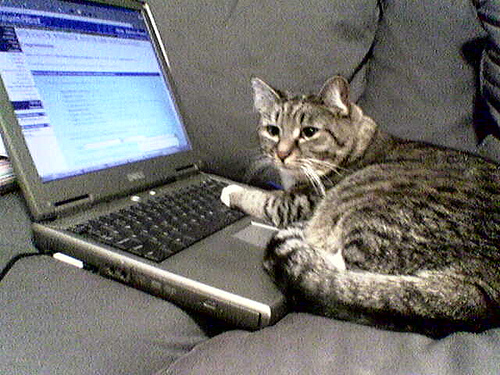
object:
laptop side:
[26, 221, 277, 329]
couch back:
[148, 1, 500, 189]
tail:
[262, 220, 500, 337]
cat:
[219, 76, 500, 330]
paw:
[216, 184, 249, 209]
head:
[249, 74, 354, 180]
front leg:
[232, 182, 331, 228]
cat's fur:
[369, 177, 491, 266]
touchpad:
[234, 221, 287, 249]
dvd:
[161, 282, 260, 334]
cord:
[0, 252, 54, 282]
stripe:
[338, 211, 411, 232]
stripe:
[339, 233, 398, 251]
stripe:
[342, 243, 375, 271]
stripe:
[340, 223, 428, 243]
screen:
[0, 0, 192, 185]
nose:
[275, 142, 290, 161]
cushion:
[153, 312, 500, 374]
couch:
[0, 0, 500, 374]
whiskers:
[238, 153, 278, 192]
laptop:
[0, 0, 290, 330]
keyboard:
[66, 180, 249, 264]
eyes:
[259, 124, 278, 137]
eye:
[296, 125, 318, 141]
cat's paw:
[219, 182, 253, 215]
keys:
[143, 249, 170, 262]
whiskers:
[293, 155, 347, 199]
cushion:
[154, 1, 382, 183]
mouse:
[224, 219, 287, 257]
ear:
[316, 74, 351, 121]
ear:
[249, 75, 279, 114]